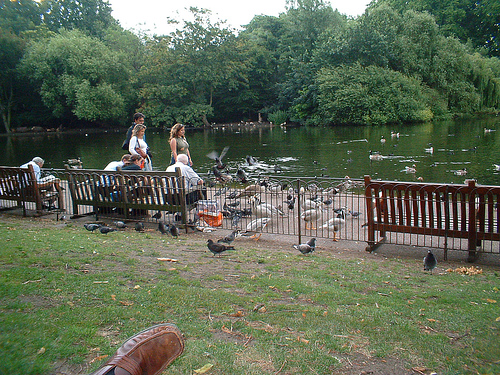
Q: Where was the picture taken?
A: It was taken at the park.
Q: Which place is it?
A: It is a park.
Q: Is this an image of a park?
A: Yes, it is showing a park.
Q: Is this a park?
A: Yes, it is a park.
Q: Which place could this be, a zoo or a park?
A: It is a park.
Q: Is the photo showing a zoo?
A: No, the picture is showing a park.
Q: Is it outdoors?
A: Yes, it is outdoors.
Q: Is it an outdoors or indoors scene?
A: It is outdoors.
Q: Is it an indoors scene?
A: No, it is outdoors.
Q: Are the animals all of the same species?
A: No, there are both pigeons and birds.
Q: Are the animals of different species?
A: Yes, they are pigeons and birds.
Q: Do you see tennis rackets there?
A: No, there are no tennis rackets.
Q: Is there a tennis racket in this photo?
A: No, there are no rackets.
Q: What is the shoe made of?
A: The shoe is made of leather.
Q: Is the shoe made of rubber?
A: No, the shoe is made of leather.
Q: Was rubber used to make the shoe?
A: No, the shoe is made of leather.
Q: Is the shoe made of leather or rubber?
A: The shoe is made of leather.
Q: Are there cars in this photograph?
A: No, there are no cars.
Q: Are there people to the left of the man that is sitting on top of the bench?
A: Yes, there is a person to the left of the man.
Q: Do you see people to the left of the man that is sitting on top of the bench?
A: Yes, there is a person to the left of the man.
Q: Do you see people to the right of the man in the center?
A: No, the person is to the left of the man.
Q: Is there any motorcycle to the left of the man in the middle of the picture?
A: No, there is a person to the left of the man.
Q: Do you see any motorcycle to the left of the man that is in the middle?
A: No, there is a person to the left of the man.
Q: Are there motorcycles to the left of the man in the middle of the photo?
A: No, there is a person to the left of the man.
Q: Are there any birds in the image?
A: Yes, there is a bird.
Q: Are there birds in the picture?
A: Yes, there is a bird.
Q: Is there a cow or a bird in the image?
A: Yes, there is a bird.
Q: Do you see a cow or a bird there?
A: Yes, there is a bird.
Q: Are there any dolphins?
A: No, there are no dolphins.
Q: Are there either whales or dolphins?
A: No, there are no dolphins or whales.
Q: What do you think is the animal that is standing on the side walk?
A: The animal is a bird.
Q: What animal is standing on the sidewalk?
A: The animal is a bird.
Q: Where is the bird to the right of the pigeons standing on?
A: The bird is standing on the sidewalk.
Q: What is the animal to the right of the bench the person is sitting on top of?
A: The animal is a bird.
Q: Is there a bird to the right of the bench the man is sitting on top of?
A: Yes, there is a bird to the right of the bench.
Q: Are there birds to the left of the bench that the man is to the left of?
A: No, the bird is to the right of the bench.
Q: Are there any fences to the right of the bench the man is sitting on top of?
A: No, there is a bird to the right of the bench.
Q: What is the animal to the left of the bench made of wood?
A: The animal is a bird.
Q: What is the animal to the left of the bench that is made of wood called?
A: The animal is a bird.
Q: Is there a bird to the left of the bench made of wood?
A: Yes, there is a bird to the left of the bench.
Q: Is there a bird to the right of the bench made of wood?
A: No, the bird is to the left of the bench.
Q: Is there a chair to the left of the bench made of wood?
A: No, there is a bird to the left of the bench.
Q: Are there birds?
A: Yes, there is a bird.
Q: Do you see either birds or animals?
A: Yes, there is a bird.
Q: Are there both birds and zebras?
A: No, there is a bird but no zebras.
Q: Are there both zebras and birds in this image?
A: No, there is a bird but no zebras.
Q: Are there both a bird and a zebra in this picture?
A: No, there is a bird but no zebras.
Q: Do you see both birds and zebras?
A: No, there is a bird but no zebras.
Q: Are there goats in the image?
A: No, there are no goats.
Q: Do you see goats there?
A: No, there are no goats.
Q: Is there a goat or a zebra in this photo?
A: No, there are no goats or zebras.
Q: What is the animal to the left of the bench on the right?
A: The animal is a bird.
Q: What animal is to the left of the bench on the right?
A: The animal is a bird.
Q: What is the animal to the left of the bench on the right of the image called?
A: The animal is a bird.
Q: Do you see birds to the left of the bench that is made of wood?
A: Yes, there is a bird to the left of the bench.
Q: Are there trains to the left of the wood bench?
A: No, there is a bird to the left of the bench.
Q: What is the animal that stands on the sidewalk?
A: The animal is a bird.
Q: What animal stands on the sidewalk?
A: The animal is a bird.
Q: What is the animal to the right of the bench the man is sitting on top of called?
A: The animal is a bird.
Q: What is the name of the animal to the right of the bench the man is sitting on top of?
A: The animal is a bird.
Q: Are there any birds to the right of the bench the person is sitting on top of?
A: Yes, there is a bird to the right of the bench.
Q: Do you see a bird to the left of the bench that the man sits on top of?
A: No, the bird is to the right of the bench.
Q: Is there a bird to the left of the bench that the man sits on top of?
A: No, the bird is to the right of the bench.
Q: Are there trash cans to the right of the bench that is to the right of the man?
A: No, there is a bird to the right of the bench.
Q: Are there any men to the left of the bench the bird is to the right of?
A: Yes, there is a man to the left of the bench.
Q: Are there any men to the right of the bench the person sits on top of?
A: No, the man is to the left of the bench.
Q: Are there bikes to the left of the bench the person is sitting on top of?
A: No, there is a man to the left of the bench.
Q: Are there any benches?
A: Yes, there is a bench.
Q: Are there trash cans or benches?
A: Yes, there is a bench.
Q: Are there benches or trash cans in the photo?
A: Yes, there is a bench.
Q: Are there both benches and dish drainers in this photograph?
A: No, there is a bench but no dish drainers.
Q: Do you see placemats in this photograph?
A: No, there are no placemats.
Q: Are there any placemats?
A: No, there are no placemats.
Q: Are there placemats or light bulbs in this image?
A: No, there are no placemats or light bulbs.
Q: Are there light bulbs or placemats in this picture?
A: No, there are no placemats or light bulbs.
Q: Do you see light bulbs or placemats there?
A: No, there are no placemats or light bulbs.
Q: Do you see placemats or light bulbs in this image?
A: No, there are no placemats or light bulbs.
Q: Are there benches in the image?
A: Yes, there is a bench.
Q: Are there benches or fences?
A: Yes, there is a bench.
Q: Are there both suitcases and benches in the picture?
A: No, there is a bench but no suitcases.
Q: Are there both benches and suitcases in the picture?
A: No, there is a bench but no suitcases.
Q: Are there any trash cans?
A: No, there are no trash cans.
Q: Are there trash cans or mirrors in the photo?
A: No, there are no trash cans or mirrors.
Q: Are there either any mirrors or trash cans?
A: No, there are no trash cans or mirrors.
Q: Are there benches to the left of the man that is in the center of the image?
A: Yes, there is a bench to the left of the man.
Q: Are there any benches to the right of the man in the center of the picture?
A: No, the bench is to the left of the man.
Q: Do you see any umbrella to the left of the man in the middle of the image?
A: No, there is a bench to the left of the man.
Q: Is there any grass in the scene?
A: Yes, there is grass.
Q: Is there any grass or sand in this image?
A: Yes, there is grass.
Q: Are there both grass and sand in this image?
A: No, there is grass but no sand.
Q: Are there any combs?
A: No, there are no combs.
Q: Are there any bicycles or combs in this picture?
A: No, there are no combs or bicycles.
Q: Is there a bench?
A: Yes, there is a bench.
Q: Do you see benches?
A: Yes, there is a bench.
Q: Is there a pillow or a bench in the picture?
A: Yes, there is a bench.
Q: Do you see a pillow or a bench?
A: Yes, there is a bench.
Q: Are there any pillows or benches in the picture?
A: Yes, there is a bench.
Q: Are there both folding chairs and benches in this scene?
A: No, there is a bench but no folding chairs.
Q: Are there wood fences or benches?
A: Yes, there is a wood bench.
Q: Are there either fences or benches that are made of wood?
A: Yes, the bench is made of wood.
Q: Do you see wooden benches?
A: Yes, there is a wood bench.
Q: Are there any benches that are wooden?
A: Yes, there is a bench that is wooden.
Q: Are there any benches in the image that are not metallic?
A: Yes, there is a wooden bench.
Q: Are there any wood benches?
A: Yes, there is a bench that is made of wood.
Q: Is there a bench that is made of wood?
A: Yes, there is a bench that is made of wood.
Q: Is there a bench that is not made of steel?
A: Yes, there is a bench that is made of wood.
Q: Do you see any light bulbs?
A: No, there are no light bulbs.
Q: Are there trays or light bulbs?
A: No, there are no light bulbs or trays.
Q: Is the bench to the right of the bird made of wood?
A: Yes, the bench is made of wood.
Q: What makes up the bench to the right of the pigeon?
A: The bench is made of wood.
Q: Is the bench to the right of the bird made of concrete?
A: No, the bench is made of wood.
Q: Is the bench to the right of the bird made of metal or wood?
A: The bench is made of wood.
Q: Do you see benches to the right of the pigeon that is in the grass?
A: Yes, there is a bench to the right of the pigeon.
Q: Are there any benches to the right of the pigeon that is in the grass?
A: Yes, there is a bench to the right of the pigeon.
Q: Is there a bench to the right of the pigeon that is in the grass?
A: Yes, there is a bench to the right of the pigeon.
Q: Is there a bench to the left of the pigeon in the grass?
A: No, the bench is to the right of the pigeon.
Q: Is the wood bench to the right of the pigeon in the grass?
A: Yes, the bench is to the right of the pigeon.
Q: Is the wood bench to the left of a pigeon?
A: No, the bench is to the right of a pigeon.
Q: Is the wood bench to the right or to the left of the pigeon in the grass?
A: The bench is to the right of the pigeon.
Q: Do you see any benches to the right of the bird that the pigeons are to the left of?
A: Yes, there is a bench to the right of the bird.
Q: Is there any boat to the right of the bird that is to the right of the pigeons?
A: No, there is a bench to the right of the bird.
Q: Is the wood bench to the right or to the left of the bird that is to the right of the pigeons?
A: The bench is to the right of the bird.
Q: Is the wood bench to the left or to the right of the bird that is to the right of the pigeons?
A: The bench is to the right of the bird.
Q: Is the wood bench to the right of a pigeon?
A: Yes, the bench is to the right of a pigeon.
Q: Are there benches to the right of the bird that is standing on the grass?
A: Yes, there is a bench to the right of the bird.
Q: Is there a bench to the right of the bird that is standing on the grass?
A: Yes, there is a bench to the right of the bird.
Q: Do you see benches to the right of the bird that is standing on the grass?
A: Yes, there is a bench to the right of the bird.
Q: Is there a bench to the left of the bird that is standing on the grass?
A: No, the bench is to the right of the bird.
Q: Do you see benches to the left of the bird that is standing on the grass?
A: No, the bench is to the right of the bird.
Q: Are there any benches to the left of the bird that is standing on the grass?
A: No, the bench is to the right of the bird.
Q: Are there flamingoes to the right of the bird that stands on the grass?
A: No, there is a bench to the right of the bird.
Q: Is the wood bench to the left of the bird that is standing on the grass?
A: No, the bench is to the right of the bird.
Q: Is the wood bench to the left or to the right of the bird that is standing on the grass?
A: The bench is to the right of the bird.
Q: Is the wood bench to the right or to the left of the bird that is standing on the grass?
A: The bench is to the right of the bird.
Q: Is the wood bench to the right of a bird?
A: Yes, the bench is to the right of a bird.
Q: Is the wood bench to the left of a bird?
A: No, the bench is to the right of a bird.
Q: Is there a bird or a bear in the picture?
A: Yes, there is a bird.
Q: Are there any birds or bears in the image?
A: Yes, there is a bird.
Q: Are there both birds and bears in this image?
A: No, there is a bird but no bears.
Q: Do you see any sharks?
A: No, there are no sharks.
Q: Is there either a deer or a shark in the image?
A: No, there are no sharks or deer.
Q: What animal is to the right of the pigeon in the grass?
A: The animal is a bird.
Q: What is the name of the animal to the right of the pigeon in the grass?
A: The animal is a bird.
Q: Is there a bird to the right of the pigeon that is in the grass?
A: Yes, there is a bird to the right of the pigeon.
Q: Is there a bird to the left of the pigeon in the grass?
A: No, the bird is to the right of the pigeon.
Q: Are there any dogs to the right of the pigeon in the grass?
A: No, there is a bird to the right of the pigeon.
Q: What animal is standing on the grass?
A: The bird is standing on the grass.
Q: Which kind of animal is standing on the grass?
A: The animal is a bird.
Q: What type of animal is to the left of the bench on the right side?
A: The animal is a bird.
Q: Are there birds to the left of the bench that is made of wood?
A: Yes, there is a bird to the left of the bench.